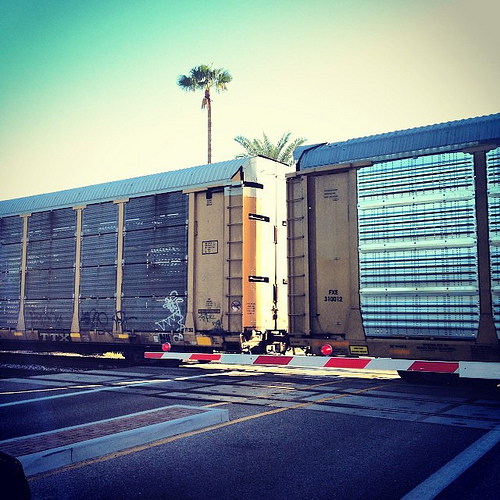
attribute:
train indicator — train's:
[316, 340, 334, 356]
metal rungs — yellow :
[283, 174, 311, 344]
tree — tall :
[165, 60, 255, 167]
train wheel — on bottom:
[116, 344, 224, 371]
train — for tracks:
[10, 189, 480, 344]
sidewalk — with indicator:
[97, 351, 444, 465]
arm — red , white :
[146, 340, 495, 387]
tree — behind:
[165, 50, 237, 171]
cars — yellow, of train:
[3, 103, 494, 372]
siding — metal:
[355, 147, 481, 341]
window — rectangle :
[241, 197, 305, 246]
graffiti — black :
[80, 306, 131, 326]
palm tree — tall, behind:
[171, 55, 259, 142]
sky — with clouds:
[0, 0, 498, 198]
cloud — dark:
[275, 44, 493, 118]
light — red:
[319, 341, 331, 356]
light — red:
[159, 341, 173, 352]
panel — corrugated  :
[346, 173, 466, 323]